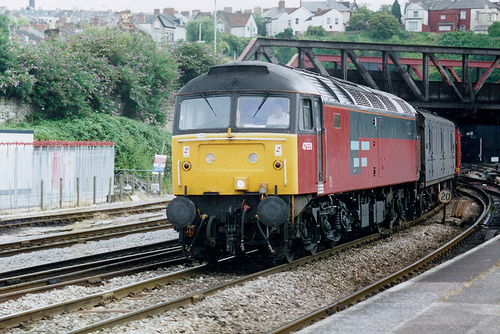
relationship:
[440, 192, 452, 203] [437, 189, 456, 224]
numbers are on front of sign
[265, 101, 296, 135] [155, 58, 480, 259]
man inside of train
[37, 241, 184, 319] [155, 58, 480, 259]
tracks are for train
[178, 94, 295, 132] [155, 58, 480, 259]
window on front of train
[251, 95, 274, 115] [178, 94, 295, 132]
wiper attached to window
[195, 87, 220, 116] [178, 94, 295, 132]
wiper attached to window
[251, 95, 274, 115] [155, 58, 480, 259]
wiper attached to train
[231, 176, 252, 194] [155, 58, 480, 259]
light attached to train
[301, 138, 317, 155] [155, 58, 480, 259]
sticker on side of train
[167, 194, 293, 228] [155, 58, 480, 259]
bumper attached to train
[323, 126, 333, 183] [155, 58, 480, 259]
rail attached to train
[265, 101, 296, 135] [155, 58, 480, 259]
man driving train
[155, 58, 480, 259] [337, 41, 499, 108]
train under bridge